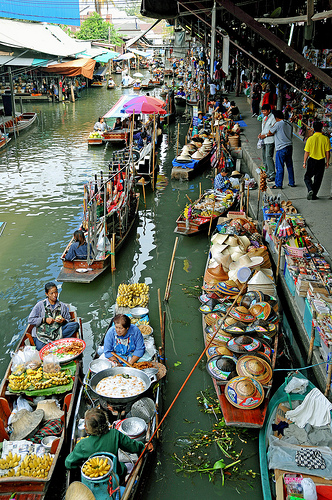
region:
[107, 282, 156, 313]
bananas on the boat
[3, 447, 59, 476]
bananas on the boat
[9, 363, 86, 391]
bananas on the boat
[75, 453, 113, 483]
bananas on the boat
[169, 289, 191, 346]
the water is murky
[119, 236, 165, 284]
the water is murky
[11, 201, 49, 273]
the water is murky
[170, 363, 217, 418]
the water is murky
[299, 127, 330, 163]
Man wearing yellow shirt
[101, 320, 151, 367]
Woman wearing blue shirt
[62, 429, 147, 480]
Woman wearing green shirt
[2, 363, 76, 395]
Yellow bananas on boat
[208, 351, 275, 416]
Three hats on a boat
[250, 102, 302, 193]
Two men standing on a platform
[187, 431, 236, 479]
Green leaves in water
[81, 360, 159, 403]
Metal bowl on boat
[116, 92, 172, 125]
Colorful umbrellas on a boat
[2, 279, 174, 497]
Two boats in the water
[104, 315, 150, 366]
guy cooking on small boat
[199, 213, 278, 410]
a small boat full of hats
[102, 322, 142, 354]
a light blue hoodie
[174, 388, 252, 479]
vegetation thrown in water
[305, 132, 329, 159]
a short sleeve yellow collard shirt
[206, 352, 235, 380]
black hat with blue decal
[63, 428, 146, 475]
a long sleeve green shirt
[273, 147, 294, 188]
a pair of blue jeans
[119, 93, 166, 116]
large red umbrellas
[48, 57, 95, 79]
an orange tarp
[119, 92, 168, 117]
rainbow umbrellas by the water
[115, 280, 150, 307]
yellow bananas on the boat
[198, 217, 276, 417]
hats on a boat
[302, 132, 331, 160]
yellow shirt on the man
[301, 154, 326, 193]
black pants on the man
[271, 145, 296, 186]
blue jeans on the man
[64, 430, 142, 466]
man in the boat wearing a green shirt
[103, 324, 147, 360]
woman in the boat wearing a blue shirt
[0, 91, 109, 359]
dirty water in the canal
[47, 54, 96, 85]
orange covering by the building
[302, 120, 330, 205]
Man in a yellow shirt walking down the street.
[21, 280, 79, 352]
A woman holding a piece of food.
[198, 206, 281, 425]
A boat full of hats.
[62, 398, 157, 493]
An old woman looking at something behind her.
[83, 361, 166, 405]
A large bowl of food.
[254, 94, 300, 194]
Two men standing on the pier.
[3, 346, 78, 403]
Several bunches of bananas on a boat.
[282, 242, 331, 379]
Stackd of books sitting on the pier.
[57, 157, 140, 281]
A young woman relaxing in a boat.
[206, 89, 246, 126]
A group of people sitting on the pier conversing.